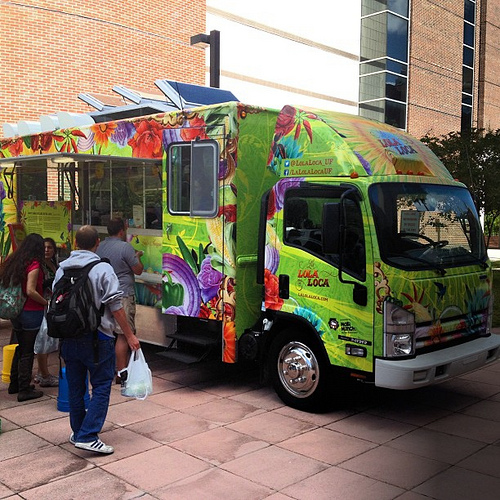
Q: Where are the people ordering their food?
A: Food truck.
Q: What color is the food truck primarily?
A: Green.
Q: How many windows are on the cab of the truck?
A: Three.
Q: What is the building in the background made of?
A: Bricks.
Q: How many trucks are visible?
A: One.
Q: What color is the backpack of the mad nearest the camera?
A: Black.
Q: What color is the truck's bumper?
A: White.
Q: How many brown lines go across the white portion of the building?
A: Two.